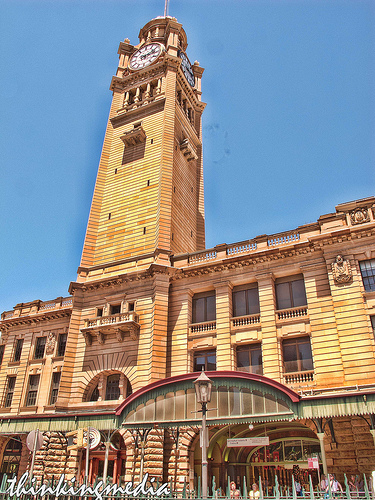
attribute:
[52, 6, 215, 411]
tower — brown, large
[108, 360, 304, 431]
archway — here, red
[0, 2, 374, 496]
building — yellow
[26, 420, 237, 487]
columns — small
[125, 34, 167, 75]
clock — large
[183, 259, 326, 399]
windows — close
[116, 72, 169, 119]
window slits — small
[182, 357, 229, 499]
light pole — tall, here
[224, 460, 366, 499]
fence — green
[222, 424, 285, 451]
sign — hanging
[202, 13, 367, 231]
sky — clear, blue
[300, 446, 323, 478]
red and white sign — here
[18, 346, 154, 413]
architecture — decorative